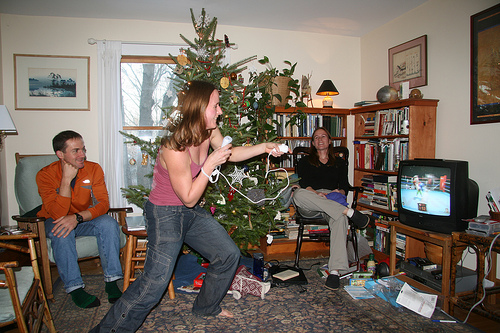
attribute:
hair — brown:
[161, 80, 217, 151]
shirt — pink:
[147, 139, 213, 207]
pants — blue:
[91, 202, 243, 331]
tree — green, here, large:
[117, 7, 292, 261]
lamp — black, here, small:
[316, 78, 340, 110]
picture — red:
[388, 33, 430, 94]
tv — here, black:
[396, 157, 479, 235]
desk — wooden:
[387, 220, 495, 312]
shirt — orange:
[36, 161, 110, 218]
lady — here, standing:
[87, 80, 292, 332]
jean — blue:
[88, 199, 242, 331]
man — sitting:
[36, 130, 126, 306]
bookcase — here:
[262, 99, 438, 262]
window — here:
[119, 57, 187, 215]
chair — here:
[15, 151, 135, 299]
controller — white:
[202, 134, 292, 204]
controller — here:
[200, 133, 234, 181]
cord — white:
[202, 150, 291, 203]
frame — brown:
[13, 53, 91, 113]